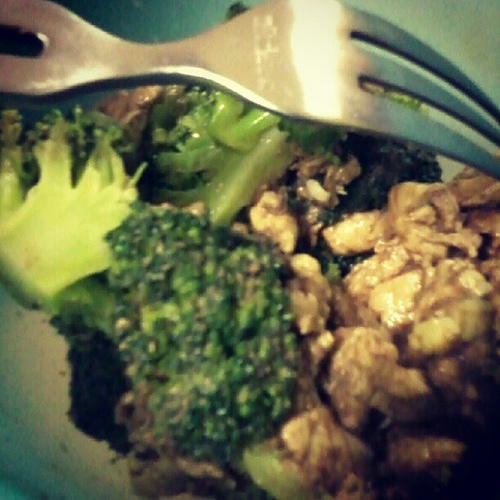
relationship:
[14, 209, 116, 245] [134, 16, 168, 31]
broccoli in bowl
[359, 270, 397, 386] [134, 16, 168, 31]
chicken in bowl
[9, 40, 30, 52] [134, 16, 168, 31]
shadow on bowl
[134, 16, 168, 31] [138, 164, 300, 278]
bowl of food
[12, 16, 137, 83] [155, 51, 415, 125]
handle of fork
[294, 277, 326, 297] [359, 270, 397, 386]
sauce on chicken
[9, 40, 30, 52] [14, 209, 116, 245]
shadow of broccoli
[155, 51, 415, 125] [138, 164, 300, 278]
fork on food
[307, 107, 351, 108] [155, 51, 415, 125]
reflection on fork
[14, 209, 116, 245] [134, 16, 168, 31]
broccoli on bowl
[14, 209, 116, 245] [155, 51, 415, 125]
broccoli near fork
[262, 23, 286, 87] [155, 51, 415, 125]
writing on fork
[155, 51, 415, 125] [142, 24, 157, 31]
fork on plate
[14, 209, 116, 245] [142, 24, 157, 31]
broccoli in plate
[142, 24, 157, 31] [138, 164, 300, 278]
plate under food